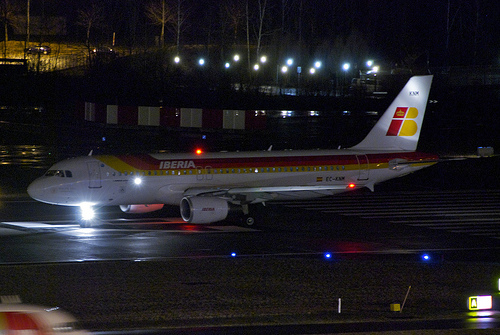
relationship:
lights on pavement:
[208, 244, 436, 261] [10, 163, 495, 317]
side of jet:
[76, 159, 391, 187] [18, 70, 467, 235]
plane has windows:
[18, 70, 467, 235] [104, 165, 369, 176]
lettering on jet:
[148, 158, 219, 179] [18, 70, 500, 235]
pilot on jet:
[49, 169, 64, 178] [18, 70, 500, 235]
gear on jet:
[235, 201, 271, 242] [18, 70, 500, 235]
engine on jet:
[178, 190, 238, 230] [18, 70, 500, 235]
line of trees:
[20, 22, 467, 84] [2, 2, 431, 98]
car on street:
[19, 43, 54, 58] [12, 49, 104, 71]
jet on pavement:
[18, 70, 500, 235] [10, 163, 495, 317]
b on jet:
[162, 160, 170, 170] [18, 70, 500, 235]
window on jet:
[46, 167, 72, 182] [18, 70, 500, 235]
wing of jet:
[223, 179, 362, 191] [18, 70, 500, 235]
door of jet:
[83, 154, 104, 191] [18, 70, 500, 235]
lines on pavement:
[310, 181, 499, 259] [9, 163, 495, 318]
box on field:
[461, 290, 494, 317] [8, 265, 500, 329]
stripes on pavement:
[310, 181, 499, 259] [10, 163, 495, 317]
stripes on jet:
[106, 154, 398, 178] [18, 70, 500, 235]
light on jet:
[185, 136, 209, 168] [18, 70, 500, 235]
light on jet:
[346, 179, 365, 203] [18, 70, 500, 235]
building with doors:
[61, 89, 301, 138] [142, 101, 166, 128]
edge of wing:
[332, 181, 345, 199] [223, 179, 362, 191]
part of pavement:
[47, 224, 485, 283] [10, 163, 495, 317]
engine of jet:
[178, 190, 238, 230] [18, 70, 500, 235]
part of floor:
[47, 224, 485, 283] [9, 163, 495, 318]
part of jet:
[337, 143, 390, 186] [18, 70, 500, 235]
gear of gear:
[235, 201, 271, 242] [235, 201, 271, 242]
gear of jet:
[235, 201, 271, 242] [18, 70, 500, 235]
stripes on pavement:
[106, 154, 398, 178] [10, 163, 495, 317]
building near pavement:
[61, 89, 301, 138] [10, 163, 495, 317]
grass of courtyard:
[8, 265, 500, 329] [8, 196, 484, 261]